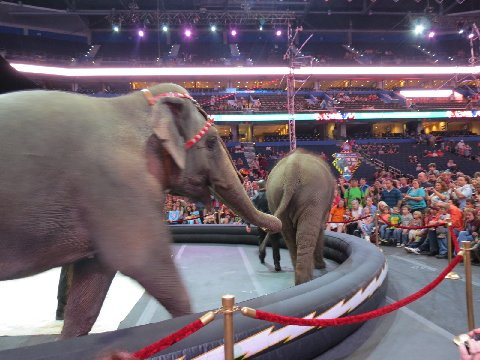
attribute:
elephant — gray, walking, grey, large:
[0, 82, 281, 342]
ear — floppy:
[151, 97, 190, 169]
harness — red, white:
[141, 81, 215, 157]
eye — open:
[207, 135, 218, 149]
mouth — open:
[204, 171, 224, 212]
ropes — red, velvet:
[132, 210, 464, 358]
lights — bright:
[8, 15, 479, 121]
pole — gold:
[460, 240, 476, 334]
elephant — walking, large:
[259, 149, 334, 282]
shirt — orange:
[330, 203, 346, 223]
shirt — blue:
[405, 187, 428, 210]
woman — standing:
[403, 177, 424, 214]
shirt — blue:
[381, 187, 402, 206]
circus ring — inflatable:
[0, 223, 388, 359]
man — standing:
[344, 178, 363, 209]